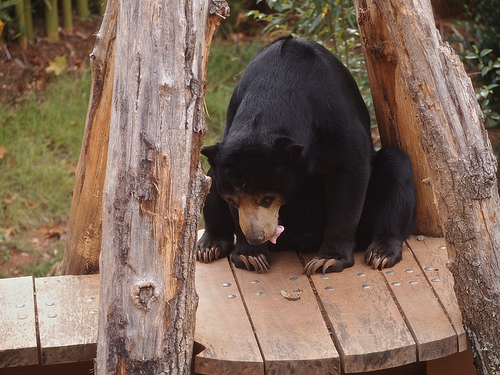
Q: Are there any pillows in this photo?
A: No, there are no pillows.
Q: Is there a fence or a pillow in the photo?
A: No, there are no pillows or fences.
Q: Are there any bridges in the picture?
A: Yes, there is a bridge.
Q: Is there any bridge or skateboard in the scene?
A: Yes, there is a bridge.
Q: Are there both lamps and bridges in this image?
A: No, there is a bridge but no lamps.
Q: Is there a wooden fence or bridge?
A: Yes, there is a wood bridge.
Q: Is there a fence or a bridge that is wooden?
A: Yes, the bridge is wooden.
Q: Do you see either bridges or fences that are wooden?
A: Yes, the bridge is wooden.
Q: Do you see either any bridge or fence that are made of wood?
A: Yes, the bridge is made of wood.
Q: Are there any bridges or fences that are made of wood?
A: Yes, the bridge is made of wood.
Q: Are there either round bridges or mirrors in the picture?
A: Yes, there is a round bridge.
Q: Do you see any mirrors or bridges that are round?
A: Yes, the bridge is round.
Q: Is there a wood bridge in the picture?
A: Yes, there is a wood bridge.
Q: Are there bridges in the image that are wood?
A: Yes, there is a wood bridge.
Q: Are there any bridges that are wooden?
A: Yes, there is a bridge that is wooden.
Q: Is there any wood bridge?
A: Yes, there is a bridge that is made of wood.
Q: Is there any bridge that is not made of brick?
A: Yes, there is a bridge that is made of wood.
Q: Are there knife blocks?
A: No, there are no knife blocks.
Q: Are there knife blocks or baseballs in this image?
A: No, there are no knife blocks or baseballs.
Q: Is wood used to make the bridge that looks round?
A: Yes, the bridge is made of wood.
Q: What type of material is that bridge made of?
A: The bridge is made of wood.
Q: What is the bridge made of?
A: The bridge is made of wood.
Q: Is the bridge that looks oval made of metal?
A: No, the bridge is made of wood.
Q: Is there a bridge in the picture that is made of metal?
A: No, there is a bridge but it is made of wood.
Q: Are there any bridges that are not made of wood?
A: No, there is a bridge but it is made of wood.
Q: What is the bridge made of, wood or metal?
A: The bridge is made of wood.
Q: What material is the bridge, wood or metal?
A: The bridge is made of wood.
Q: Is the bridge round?
A: Yes, the bridge is round.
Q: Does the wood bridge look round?
A: Yes, the bridge is round.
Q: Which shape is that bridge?
A: The bridge is round.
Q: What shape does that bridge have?
A: The bridge has round shape.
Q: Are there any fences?
A: No, there are no fences.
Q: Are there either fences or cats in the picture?
A: No, there are no fences or cats.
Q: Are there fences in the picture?
A: No, there are no fences.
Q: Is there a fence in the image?
A: No, there are no fences.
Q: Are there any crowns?
A: No, there are no crowns.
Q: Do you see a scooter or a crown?
A: No, there are no crowns or scooters.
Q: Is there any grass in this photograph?
A: Yes, there is grass.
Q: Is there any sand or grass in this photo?
A: Yes, there is grass.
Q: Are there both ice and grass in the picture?
A: No, there is grass but no ice.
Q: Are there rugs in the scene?
A: No, there are no rugs.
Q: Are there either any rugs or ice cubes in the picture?
A: No, there are no rugs or ice cubes.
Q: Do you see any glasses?
A: No, there are no glasses.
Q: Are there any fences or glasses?
A: No, there are no glasses or fences.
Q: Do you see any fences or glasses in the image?
A: No, there are no glasses or fences.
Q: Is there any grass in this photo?
A: Yes, there is grass.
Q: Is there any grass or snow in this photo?
A: Yes, there is grass.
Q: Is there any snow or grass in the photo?
A: Yes, there is grass.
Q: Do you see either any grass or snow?
A: Yes, there is grass.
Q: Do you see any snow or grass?
A: Yes, there is grass.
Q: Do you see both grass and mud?
A: No, there is grass but no mud.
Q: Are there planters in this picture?
A: No, there are no planters.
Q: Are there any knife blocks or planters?
A: No, there are no planters or knife blocks.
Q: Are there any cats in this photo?
A: No, there are no cats.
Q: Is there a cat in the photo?
A: No, there are no cats.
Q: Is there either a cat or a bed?
A: No, there are no cats or beds.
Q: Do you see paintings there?
A: No, there are no paintings.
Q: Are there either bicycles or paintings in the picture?
A: No, there are no paintings or bicycles.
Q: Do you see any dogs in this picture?
A: No, there are no dogs.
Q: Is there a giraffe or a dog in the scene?
A: No, there are no dogs or giraffes.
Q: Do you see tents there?
A: No, there are no tents.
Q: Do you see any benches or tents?
A: No, there are no tents or benches.